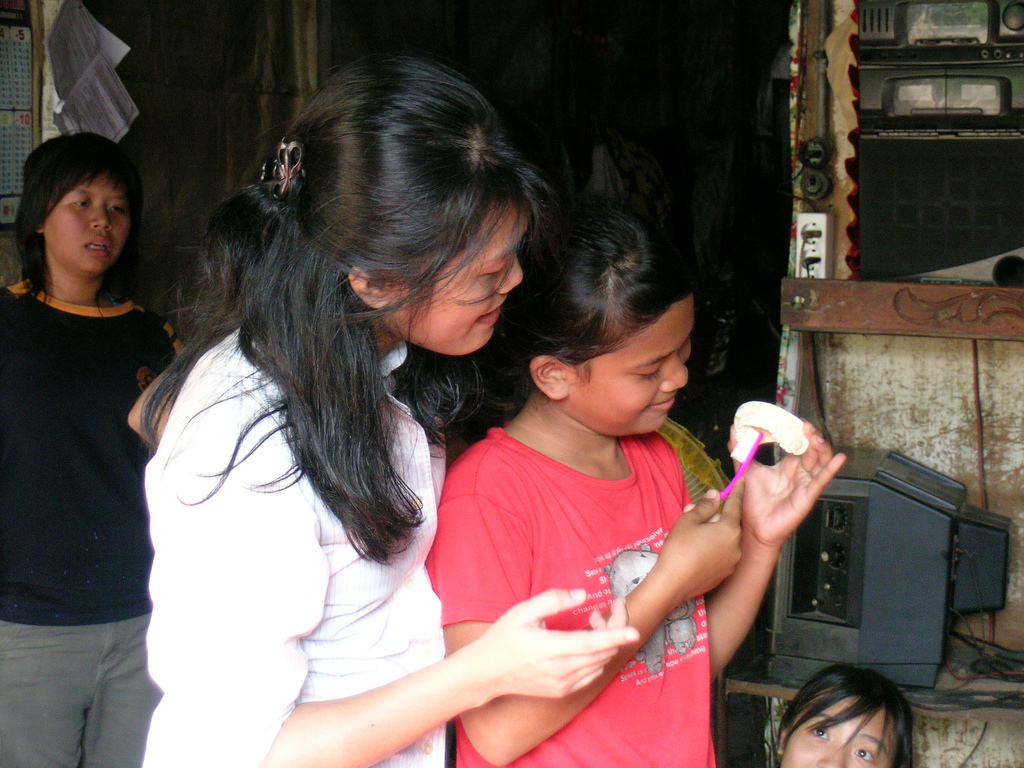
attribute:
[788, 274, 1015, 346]
shelf — wooden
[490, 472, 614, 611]
shirt — red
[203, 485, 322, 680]
sweater — white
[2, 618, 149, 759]
pants — grey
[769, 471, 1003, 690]
television —  black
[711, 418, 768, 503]
toothbrush — pink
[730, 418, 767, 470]
bristles — white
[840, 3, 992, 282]
stereo system — old, black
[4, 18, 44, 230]
wall callender — blue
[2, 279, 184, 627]
shirt — black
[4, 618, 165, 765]
pants — gray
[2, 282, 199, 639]
shirt — black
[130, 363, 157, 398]
accent — gold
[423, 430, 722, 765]
top — red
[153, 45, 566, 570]
hair — black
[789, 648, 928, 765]
hair — black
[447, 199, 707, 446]
hair — black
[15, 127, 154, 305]
hair — black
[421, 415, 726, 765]
shirt — pink, red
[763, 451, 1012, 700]
tv — black, old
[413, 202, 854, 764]
person — standing up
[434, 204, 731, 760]
person — standing up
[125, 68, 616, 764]
person — standing up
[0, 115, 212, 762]
person — standing up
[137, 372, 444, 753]
shirt — white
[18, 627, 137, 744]
pants — gray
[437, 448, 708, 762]
shirt — pinkish red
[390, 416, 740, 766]
shirt — red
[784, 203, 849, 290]
outlet — white, electrical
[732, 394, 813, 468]
teeth — false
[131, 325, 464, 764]
shirt — white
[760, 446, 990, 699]
television — old, black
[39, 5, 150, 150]
papers — white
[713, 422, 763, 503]
toothbrush — pink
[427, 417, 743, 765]
tee shirt — pink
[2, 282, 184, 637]
sweater — black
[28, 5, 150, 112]
paper — white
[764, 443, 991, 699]
box — gray